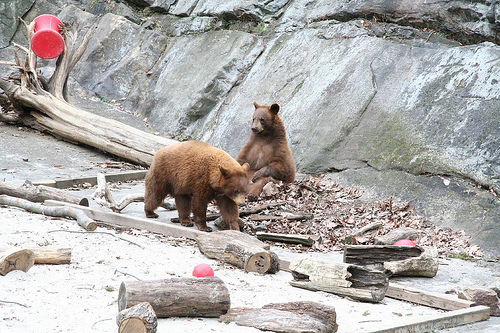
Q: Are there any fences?
A: No, there are no fences.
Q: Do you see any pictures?
A: No, there are no pictures.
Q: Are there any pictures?
A: No, there are no pictures.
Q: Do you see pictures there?
A: No, there are no pictures.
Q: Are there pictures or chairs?
A: No, there are no pictures or chairs.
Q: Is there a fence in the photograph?
A: No, there are no fences.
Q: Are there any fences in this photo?
A: No, there are no fences.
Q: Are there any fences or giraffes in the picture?
A: No, there are no fences or giraffes.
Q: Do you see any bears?
A: Yes, there is a bear.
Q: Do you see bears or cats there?
A: Yes, there is a bear.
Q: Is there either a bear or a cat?
A: Yes, there is a bear.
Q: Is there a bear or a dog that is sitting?
A: Yes, the bear is sitting.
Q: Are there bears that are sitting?
A: Yes, there is a bear that is sitting.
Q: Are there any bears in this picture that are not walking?
A: Yes, there is a bear that is sitting.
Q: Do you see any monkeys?
A: No, there are no monkeys.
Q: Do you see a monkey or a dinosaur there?
A: No, there are no monkeys or dinosaurs.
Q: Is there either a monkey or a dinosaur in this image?
A: No, there are no monkeys or dinosaurs.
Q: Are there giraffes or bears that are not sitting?
A: No, there is a bear but it is sitting.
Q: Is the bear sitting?
A: Yes, the bear is sitting.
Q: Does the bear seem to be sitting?
A: Yes, the bear is sitting.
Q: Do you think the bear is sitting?
A: Yes, the bear is sitting.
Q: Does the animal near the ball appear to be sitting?
A: Yes, the bear is sitting.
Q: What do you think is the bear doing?
A: The bear is sitting.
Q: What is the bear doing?
A: The bear is sitting.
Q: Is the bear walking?
A: No, the bear is sitting.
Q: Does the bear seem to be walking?
A: No, the bear is sitting.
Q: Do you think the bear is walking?
A: No, the bear is sitting.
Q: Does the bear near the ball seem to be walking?
A: No, the bear is sitting.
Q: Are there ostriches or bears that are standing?
A: No, there is a bear but it is sitting.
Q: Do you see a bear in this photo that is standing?
A: No, there is a bear but it is sitting.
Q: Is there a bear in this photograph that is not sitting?
A: No, there is a bear but it is sitting.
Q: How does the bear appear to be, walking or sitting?
A: The bear is sitting.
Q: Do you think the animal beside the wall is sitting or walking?
A: The bear is sitting.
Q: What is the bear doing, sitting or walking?
A: The bear is sitting.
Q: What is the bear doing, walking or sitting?
A: The bear is sitting.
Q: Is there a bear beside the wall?
A: Yes, there is a bear beside the wall.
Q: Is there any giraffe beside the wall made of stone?
A: No, there is a bear beside the wall.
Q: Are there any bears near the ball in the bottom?
A: Yes, there is a bear near the ball.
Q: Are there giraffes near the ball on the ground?
A: No, there is a bear near the ball.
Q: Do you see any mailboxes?
A: No, there are no mailboxes.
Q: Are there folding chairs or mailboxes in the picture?
A: No, there are no mailboxes or folding chairs.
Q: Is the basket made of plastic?
A: Yes, the basket is made of plastic.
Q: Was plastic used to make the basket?
A: Yes, the basket is made of plastic.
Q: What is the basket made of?
A: The basket is made of plastic.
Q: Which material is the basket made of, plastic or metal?
A: The basket is made of plastic.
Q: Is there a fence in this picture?
A: No, there are no fences.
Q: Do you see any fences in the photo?
A: No, there are no fences.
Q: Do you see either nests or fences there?
A: No, there are no fences or nests.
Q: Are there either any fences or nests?
A: No, there are no fences or nests.